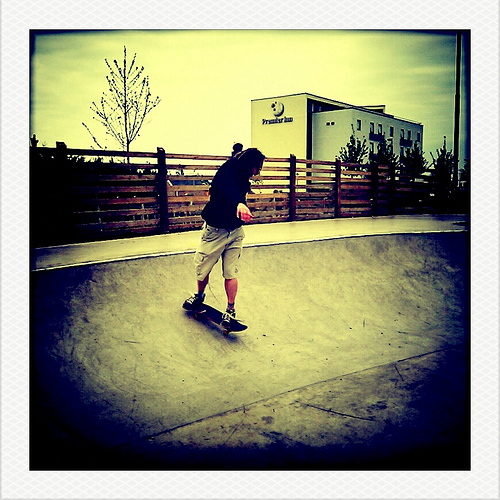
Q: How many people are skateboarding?
A: 1.